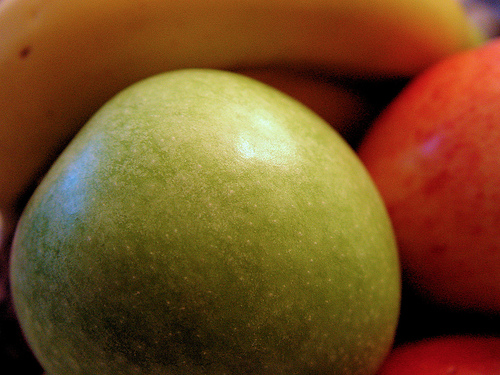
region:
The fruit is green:
[36, 64, 404, 350]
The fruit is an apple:
[17, 58, 435, 347]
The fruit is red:
[348, 33, 495, 333]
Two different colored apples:
[11, 33, 496, 369]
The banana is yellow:
[8, 6, 468, 173]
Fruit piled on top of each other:
[17, 11, 479, 358]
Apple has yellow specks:
[65, 168, 364, 339]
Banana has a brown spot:
[3, 13, 83, 89]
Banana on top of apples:
[18, 6, 465, 197]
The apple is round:
[15, 46, 426, 372]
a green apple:
[14, 21, 434, 371]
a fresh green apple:
[44, 38, 440, 373]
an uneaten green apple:
[28, 27, 469, 361]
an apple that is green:
[1, 40, 416, 374]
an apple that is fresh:
[12, 40, 447, 373]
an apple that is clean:
[16, 77, 411, 357]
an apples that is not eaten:
[30, 39, 455, 373]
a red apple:
[347, 27, 497, 333]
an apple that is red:
[358, 27, 497, 293]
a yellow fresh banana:
[4, 2, 499, 177]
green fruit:
[11, 67, 393, 357]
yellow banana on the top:
[16, 3, 456, 118]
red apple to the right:
[362, 40, 497, 273]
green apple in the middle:
[27, 77, 375, 353]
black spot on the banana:
[11, 17, 60, 74]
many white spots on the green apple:
[84, 155, 392, 363]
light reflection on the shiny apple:
[31, 97, 327, 239]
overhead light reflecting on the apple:
[39, 110, 311, 237]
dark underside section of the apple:
[65, 256, 382, 365]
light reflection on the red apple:
[396, 117, 460, 169]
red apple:
[358, 40, 498, 312]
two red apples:
[358, 47, 499, 369]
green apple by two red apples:
[12, 72, 467, 374]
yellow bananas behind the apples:
[4, 6, 497, 173]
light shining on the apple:
[222, 119, 319, 177]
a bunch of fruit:
[2, 4, 499, 368]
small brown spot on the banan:
[16, 40, 46, 80]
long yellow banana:
[4, 5, 493, 136]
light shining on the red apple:
[416, 127, 450, 161]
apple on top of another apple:
[377, 30, 497, 373]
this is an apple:
[122, 154, 310, 333]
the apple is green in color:
[176, 181, 299, 290]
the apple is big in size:
[98, 130, 323, 337]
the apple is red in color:
[393, 80, 483, 164]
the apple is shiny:
[233, 119, 295, 163]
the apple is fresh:
[151, 215, 258, 326]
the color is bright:
[420, 74, 483, 183]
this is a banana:
[184, 15, 281, 67]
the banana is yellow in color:
[264, 7, 339, 54]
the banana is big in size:
[139, 6, 213, 60]